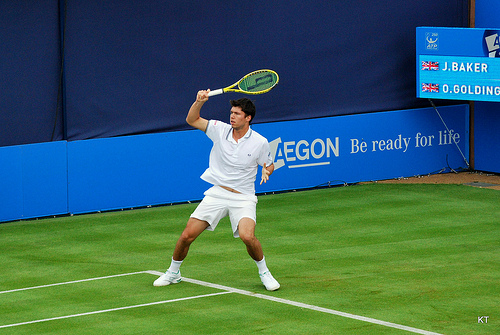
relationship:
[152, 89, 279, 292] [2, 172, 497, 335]
man on court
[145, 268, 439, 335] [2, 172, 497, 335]
line on court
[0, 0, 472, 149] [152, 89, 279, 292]
wall behind man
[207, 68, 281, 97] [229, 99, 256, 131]
racket above head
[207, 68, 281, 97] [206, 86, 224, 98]
racket has handle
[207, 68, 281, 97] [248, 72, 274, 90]
racket has initial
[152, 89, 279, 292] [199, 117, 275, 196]
man wearing shirt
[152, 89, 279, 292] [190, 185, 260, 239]
man wearing shorts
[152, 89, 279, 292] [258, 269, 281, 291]
man wearing shoe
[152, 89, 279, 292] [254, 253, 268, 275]
man wearing sock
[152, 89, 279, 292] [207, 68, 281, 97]
man holding racket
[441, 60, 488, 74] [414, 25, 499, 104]
word on scoreboard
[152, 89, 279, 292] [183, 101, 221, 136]
man has arm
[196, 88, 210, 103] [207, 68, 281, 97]
hand holding racket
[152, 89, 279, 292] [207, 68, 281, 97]
man swinging racket